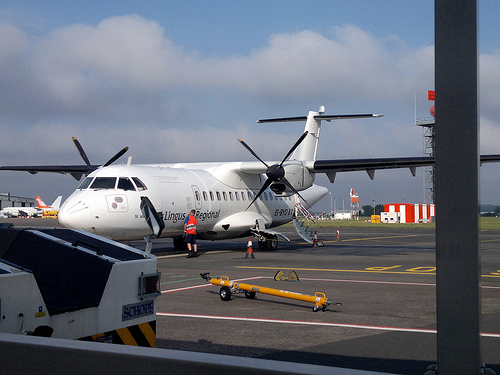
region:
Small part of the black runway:
[366, 293, 404, 322]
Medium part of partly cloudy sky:
[125, 74, 207, 116]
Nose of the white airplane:
[56, 205, 73, 225]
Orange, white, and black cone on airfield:
[240, 233, 261, 266]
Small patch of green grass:
[338, 220, 347, 228]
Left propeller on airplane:
[233, 135, 307, 214]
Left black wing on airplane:
[323, 155, 430, 178]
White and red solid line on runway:
[204, 309, 311, 336]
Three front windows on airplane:
[85, 175, 132, 190]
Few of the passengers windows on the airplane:
[196, 188, 246, 206]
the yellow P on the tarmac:
[363, 265, 399, 271]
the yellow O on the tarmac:
[406, 263, 436, 273]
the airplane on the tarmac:
[0, 105, 499, 251]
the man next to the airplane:
[181, 208, 199, 258]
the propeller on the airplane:
[236, 130, 311, 212]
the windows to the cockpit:
[76, 175, 148, 192]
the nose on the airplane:
[56, 197, 91, 228]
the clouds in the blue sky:
[1, 0, 498, 207]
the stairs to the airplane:
[291, 213, 326, 245]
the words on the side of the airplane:
[163, 208, 221, 222]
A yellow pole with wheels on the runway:
[206, 265, 338, 317]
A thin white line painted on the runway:
[159, 304, 437, 344]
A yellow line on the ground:
[231, 258, 368, 278]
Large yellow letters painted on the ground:
[365, 253, 499, 293]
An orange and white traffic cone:
[243, 235, 260, 258]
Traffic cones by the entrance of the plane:
[310, 220, 351, 252]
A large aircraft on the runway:
[64, 131, 351, 259]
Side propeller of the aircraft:
[240, 135, 315, 211]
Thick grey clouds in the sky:
[38, 32, 380, 113]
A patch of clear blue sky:
[192, 13, 250, 46]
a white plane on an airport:
[1, 96, 413, 265]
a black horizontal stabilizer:
[250, 107, 387, 127]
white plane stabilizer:
[292, 103, 328, 167]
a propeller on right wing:
[232, 133, 321, 218]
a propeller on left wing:
[53, 127, 125, 173]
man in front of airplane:
[140, 180, 210, 260]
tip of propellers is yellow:
[227, 128, 274, 169]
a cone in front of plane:
[234, 229, 264, 268]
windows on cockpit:
[54, 163, 157, 229]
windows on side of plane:
[183, 180, 308, 211]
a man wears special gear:
[180, 207, 200, 262]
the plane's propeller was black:
[237, 132, 302, 211]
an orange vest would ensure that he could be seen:
[183, 205, 203, 260]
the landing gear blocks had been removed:
[270, 269, 300, 286]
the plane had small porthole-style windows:
[190, 187, 272, 203]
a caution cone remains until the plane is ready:
[240, 234, 257, 259]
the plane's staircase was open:
[292, 200, 325, 250]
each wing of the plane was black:
[312, 149, 477, 176]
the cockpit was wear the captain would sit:
[82, 168, 139, 198]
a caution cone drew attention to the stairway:
[311, 229, 318, 246]